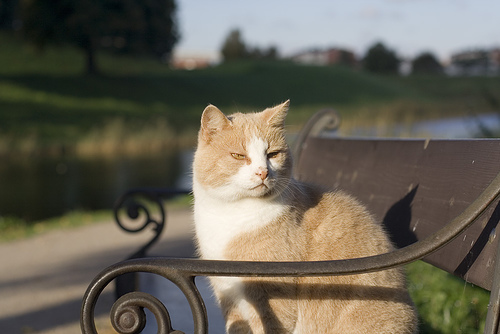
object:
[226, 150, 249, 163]
eye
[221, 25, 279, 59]
trees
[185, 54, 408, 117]
hill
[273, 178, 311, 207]
whisker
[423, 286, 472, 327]
grass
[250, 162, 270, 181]
nose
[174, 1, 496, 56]
sky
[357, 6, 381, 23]
cloud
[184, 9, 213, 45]
cloud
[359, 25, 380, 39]
cloud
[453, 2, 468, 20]
cloud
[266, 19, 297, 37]
cloud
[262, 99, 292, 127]
ear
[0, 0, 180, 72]
tree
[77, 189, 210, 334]
design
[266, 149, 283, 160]
eye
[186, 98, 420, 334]
cat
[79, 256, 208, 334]
arm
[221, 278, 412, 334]
shadow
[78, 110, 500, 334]
bench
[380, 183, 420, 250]
shadow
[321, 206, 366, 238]
fur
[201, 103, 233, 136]
ear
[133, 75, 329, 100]
grass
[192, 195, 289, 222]
neck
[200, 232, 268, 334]
belly